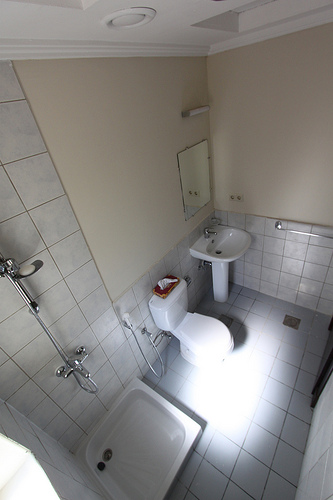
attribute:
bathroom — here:
[41, 28, 284, 411]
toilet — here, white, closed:
[136, 261, 245, 357]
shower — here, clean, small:
[14, 211, 159, 463]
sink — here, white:
[187, 218, 258, 304]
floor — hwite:
[161, 298, 305, 409]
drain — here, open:
[276, 306, 306, 335]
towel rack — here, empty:
[275, 213, 322, 254]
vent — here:
[112, 7, 142, 44]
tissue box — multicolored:
[149, 271, 186, 305]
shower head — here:
[11, 248, 52, 302]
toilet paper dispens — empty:
[177, 268, 196, 287]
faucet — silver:
[198, 220, 215, 243]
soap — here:
[86, 461, 114, 471]